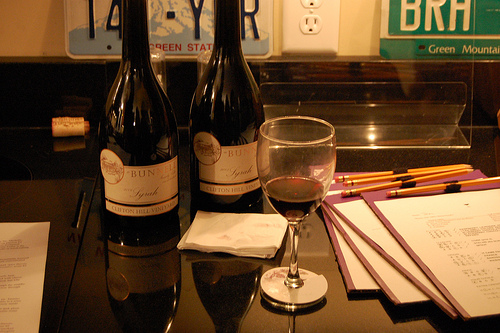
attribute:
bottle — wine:
[96, 1, 178, 224]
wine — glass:
[263, 175, 328, 216]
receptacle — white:
[282, 0, 340, 58]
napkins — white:
[175, 209, 289, 261]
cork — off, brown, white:
[48, 114, 92, 140]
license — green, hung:
[380, 2, 499, 62]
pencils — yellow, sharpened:
[335, 163, 498, 200]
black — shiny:
[50, 249, 332, 332]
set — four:
[328, 172, 499, 321]